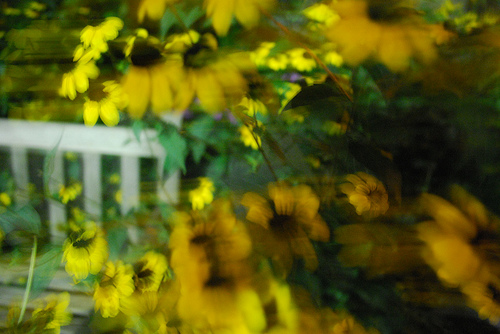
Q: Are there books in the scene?
A: No, there are no books.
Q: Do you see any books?
A: No, there are no books.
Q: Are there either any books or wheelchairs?
A: No, there are no books or wheelchairs.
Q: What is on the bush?
A: The flower is on the bush.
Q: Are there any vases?
A: No, there are no vases.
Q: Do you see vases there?
A: No, there are no vases.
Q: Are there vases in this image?
A: No, there are no vases.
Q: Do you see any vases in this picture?
A: No, there are no vases.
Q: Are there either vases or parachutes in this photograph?
A: No, there are no vases or parachutes.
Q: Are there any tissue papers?
A: No, there are no tissue papers.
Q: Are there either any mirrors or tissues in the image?
A: No, there are no tissues or mirrors.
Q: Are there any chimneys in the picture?
A: No, there are no chimneys.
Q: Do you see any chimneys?
A: No, there are no chimneys.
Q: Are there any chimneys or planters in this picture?
A: No, there are no chimneys or planters.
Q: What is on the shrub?
A: The flower is on the shrub.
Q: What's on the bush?
A: The flower is on the shrub.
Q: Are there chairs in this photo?
A: No, there are no chairs.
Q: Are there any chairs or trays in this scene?
A: No, there are no chairs or trays.